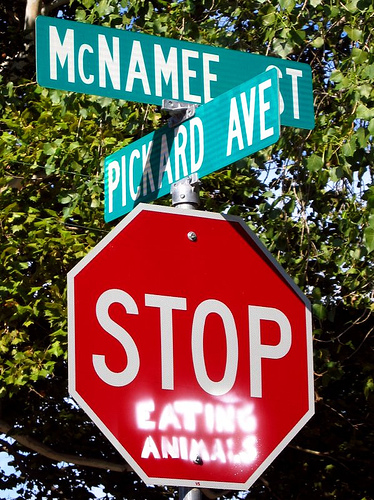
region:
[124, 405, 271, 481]
White lettering on red sign.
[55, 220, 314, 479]
Large red stop sign.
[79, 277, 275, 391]
Stop written in white letters.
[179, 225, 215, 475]
2 screws connecting sign to pole.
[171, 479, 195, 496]
Pole is silver attached to signs.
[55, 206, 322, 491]
White outline on edge of sign.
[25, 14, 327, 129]
Green street sign on top of pole.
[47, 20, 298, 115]
White lettering on street sign.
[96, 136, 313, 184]
Green street sign above stop sign.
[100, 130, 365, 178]
White lettering on green sign.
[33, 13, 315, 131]
green sign is McNamee St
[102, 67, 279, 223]
green sign is Pickard Ave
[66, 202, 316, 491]
stop sign is red and white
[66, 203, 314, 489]
stop sign is octagon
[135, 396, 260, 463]
stop sign is vandalized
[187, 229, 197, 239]
top metal screw in stop sign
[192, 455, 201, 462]
bottom metal screw in stop sign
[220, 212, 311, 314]
shadow on stop sign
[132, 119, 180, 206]
shadow on street sign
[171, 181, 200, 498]
silver stop sign pole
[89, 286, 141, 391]
white letter on a sign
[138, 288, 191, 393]
white letter on a sign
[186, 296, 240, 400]
white letter on a sign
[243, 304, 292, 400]
white letter on a sign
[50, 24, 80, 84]
white letter on a sign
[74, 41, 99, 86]
white letter on a sign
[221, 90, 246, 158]
white letter on a sign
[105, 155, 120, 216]
white letter on a sign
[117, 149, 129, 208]
white letter on a sign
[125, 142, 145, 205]
white letter on a sign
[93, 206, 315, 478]
Red and white sign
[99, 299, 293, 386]
white letters on the sign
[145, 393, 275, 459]
hand writing on the sign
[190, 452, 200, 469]
bolt on the sign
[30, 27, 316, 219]
signs on top of a sign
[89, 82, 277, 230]
a green and white sign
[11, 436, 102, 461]
a tree limb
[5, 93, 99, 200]
leaves on a tree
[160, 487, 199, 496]
part of a pole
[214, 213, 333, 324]
shadow on a sign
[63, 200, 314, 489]
Traffic stop sign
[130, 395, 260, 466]
White graffiti on stop sign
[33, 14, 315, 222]
Aluminum street signs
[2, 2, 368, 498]
Traffic signs in front of trees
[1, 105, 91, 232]
Green leaves on a tree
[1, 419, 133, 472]
Brown tree branch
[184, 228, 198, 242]
Metal stop sign screw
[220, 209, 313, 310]
Shadow on stop sign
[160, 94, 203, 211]
Pole supporting traffic signs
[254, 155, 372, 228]
Clear sky behind leaves